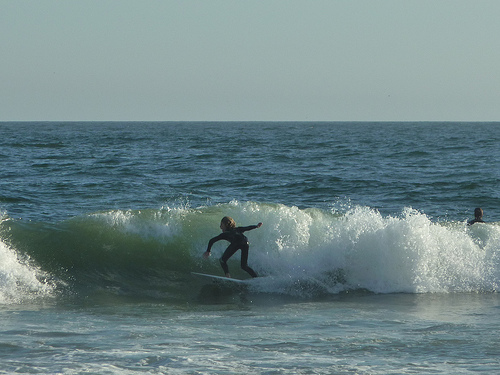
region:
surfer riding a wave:
[181, 195, 283, 295]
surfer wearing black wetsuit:
[200, 206, 267, 291]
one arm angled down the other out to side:
[200, 200, 265, 261]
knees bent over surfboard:
[212, 245, 257, 285]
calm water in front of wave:
[46, 270, 461, 360]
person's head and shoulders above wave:
[455, 197, 490, 293]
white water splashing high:
[270, 195, 476, 285]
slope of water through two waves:
[1, 200, 171, 305]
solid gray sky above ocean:
[86, 31, 352, 146]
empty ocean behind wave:
[58, 127, 454, 212]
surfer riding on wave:
[182, 205, 279, 298]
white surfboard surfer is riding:
[190, 263, 262, 295]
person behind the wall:
[459, 200, 491, 230]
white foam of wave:
[2, 205, 498, 320]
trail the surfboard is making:
[237, 267, 325, 297]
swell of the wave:
[14, 200, 229, 293]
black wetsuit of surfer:
[208, 228, 254, 272]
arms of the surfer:
[200, 221, 264, 258]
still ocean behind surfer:
[2, 121, 489, 213]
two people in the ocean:
[197, 188, 490, 281]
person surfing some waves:
[112, 163, 330, 314]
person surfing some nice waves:
[97, 163, 333, 330]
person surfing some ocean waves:
[141, 165, 332, 336]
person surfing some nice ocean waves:
[128, 176, 323, 323]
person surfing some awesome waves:
[159, 171, 322, 337]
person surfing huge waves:
[125, 160, 352, 341]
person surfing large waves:
[135, 166, 331, 336]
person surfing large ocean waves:
[134, 170, 323, 341]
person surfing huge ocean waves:
[124, 156, 340, 335]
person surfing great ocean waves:
[98, 166, 348, 341]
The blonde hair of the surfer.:
[220, 213, 235, 231]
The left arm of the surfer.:
[204, 234, 219, 257]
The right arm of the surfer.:
[245, 222, 270, 232]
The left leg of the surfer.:
[215, 249, 232, 274]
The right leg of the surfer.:
[239, 250, 255, 277]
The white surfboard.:
[183, 268, 272, 296]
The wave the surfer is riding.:
[25, 201, 499, 310]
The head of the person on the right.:
[471, 201, 487, 218]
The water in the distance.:
[4, 118, 494, 221]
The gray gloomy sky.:
[4, 1, 498, 130]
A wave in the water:
[18, 211, 188, 282]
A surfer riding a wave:
[201, 212, 261, 289]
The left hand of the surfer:
[256, 215, 270, 231]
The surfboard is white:
[191, 269, 243, 287]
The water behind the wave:
[171, 125, 491, 187]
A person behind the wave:
[464, 201, 489, 226]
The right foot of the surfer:
[222, 269, 233, 278]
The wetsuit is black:
[210, 230, 256, 277]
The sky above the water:
[10, 4, 486, 114]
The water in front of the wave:
[75, 308, 487, 369]